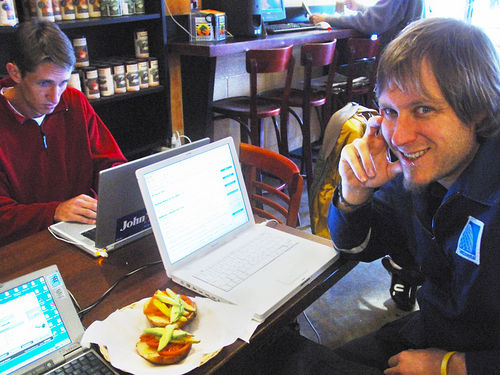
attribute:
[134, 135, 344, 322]
laptop — white, apple brand, open, on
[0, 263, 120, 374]
laptop — open, on, silver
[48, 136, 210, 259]
laptop — open, silver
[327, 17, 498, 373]
man — smiling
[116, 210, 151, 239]
sticker — black, political, bumper sticker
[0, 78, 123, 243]
shirt — red, sweatshirt, pull-over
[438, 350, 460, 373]
band — yellow, rubber, wrist band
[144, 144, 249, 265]
screen — on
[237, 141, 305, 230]
chair — wooden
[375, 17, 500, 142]
hair — long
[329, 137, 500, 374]
jacket — blue, zip-up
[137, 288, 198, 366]
food — healthy, a burger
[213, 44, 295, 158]
bar stool — wooden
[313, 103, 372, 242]
rain jacket — yellow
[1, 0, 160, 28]
tea — neat